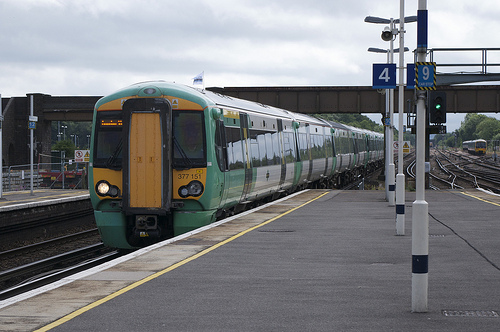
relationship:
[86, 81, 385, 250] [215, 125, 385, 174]
train has a side windows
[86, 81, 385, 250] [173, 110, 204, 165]
train has a window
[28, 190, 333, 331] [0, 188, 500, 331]
line on pavement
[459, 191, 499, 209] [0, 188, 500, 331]
line on pavement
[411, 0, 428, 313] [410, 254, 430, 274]
white post has a blue section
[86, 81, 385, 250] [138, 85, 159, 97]
train has a curved light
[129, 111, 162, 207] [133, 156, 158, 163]
yellow door has handles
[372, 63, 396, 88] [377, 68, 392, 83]
blue sign has a white number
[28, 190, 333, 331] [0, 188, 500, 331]
line painted on asphalt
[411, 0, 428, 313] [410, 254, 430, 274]
white pole has a blue stripe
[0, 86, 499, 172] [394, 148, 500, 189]
bridge over train tracks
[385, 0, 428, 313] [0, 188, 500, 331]
white poles are on train platform